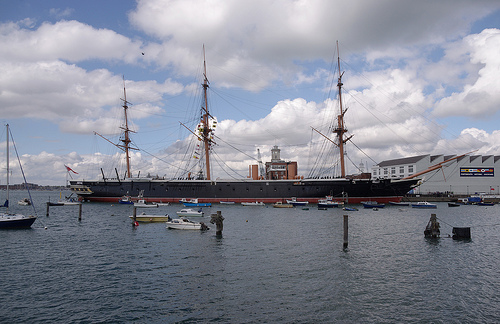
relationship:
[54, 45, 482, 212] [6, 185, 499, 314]
ship in water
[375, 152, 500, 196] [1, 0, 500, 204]
building in background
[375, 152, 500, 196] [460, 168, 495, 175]
building has a sign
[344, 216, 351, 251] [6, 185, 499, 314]
pole in water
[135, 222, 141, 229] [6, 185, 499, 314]
bowie in water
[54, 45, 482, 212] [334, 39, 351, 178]
ship has a mast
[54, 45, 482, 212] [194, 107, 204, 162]
ship has a flag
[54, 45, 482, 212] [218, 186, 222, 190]
ship has a window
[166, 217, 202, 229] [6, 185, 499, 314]
boat in water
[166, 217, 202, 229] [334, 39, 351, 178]
boat has a mast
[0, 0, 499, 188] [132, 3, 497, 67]
sky has clouds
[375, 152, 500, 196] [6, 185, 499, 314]
building close to water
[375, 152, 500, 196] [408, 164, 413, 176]
building has a window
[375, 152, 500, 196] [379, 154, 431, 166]
building has a roof